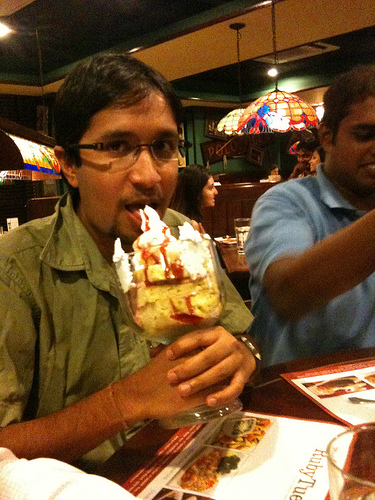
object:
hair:
[169, 163, 212, 225]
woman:
[168, 162, 218, 235]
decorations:
[200, 88, 321, 167]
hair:
[46, 48, 187, 213]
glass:
[110, 237, 244, 427]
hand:
[166, 323, 256, 408]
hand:
[140, 341, 227, 427]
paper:
[119, 405, 359, 500]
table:
[3, 347, 375, 500]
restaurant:
[0, 0, 375, 500]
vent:
[254, 42, 341, 64]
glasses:
[55, 130, 190, 161]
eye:
[102, 134, 174, 156]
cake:
[112, 204, 229, 346]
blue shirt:
[243, 162, 374, 364]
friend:
[244, 59, 373, 364]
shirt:
[0, 193, 251, 472]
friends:
[287, 138, 324, 179]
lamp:
[214, 2, 321, 145]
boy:
[289, 139, 315, 180]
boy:
[241, 62, 375, 366]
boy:
[3, 46, 264, 459]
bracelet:
[106, 381, 132, 434]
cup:
[326, 421, 374, 486]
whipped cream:
[113, 201, 215, 295]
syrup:
[141, 244, 184, 285]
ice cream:
[110, 202, 227, 345]